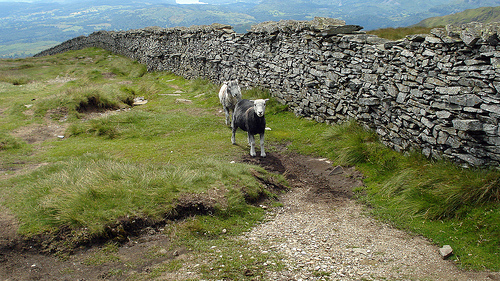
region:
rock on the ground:
[435, 239, 457, 262]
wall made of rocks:
[446, 46, 498, 151]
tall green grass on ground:
[435, 173, 499, 208]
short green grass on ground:
[435, 226, 457, 241]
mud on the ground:
[308, 166, 340, 192]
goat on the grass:
[231, 97, 278, 158]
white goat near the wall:
[211, 78, 242, 109]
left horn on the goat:
[264, 95, 272, 106]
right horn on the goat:
[249, 97, 256, 104]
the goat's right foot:
[243, 131, 258, 156]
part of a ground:
[281, 218, 326, 255]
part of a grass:
[203, 185, 224, 212]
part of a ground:
[327, 237, 352, 272]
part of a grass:
[194, 181, 222, 218]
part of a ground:
[303, 233, 324, 259]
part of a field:
[171, 155, 209, 205]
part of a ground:
[319, 205, 342, 255]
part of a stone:
[436, 236, 448, 267]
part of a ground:
[302, 246, 317, 269]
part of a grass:
[158, 163, 206, 222]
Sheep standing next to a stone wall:
[66, 14, 422, 251]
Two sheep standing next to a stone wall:
[199, 19, 322, 162]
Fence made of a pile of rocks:
[311, 8, 488, 193]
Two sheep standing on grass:
[171, 70, 292, 173]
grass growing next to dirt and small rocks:
[320, 152, 402, 257]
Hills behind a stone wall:
[48, 1, 343, 49]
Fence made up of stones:
[105, 20, 200, 91]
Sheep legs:
[207, 130, 273, 160]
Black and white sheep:
[225, 98, 278, 158]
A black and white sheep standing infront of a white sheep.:
[196, 73, 289, 170]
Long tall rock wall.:
[87, 27, 494, 141]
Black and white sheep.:
[230, 97, 271, 157]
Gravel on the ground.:
[260, 202, 422, 279]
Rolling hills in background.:
[5, 0, 440, 30]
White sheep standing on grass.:
[217, 78, 241, 123]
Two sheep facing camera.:
[216, 79, 268, 161]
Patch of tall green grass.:
[17, 148, 217, 223]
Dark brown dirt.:
[5, 220, 177, 277]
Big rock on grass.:
[437, 237, 452, 262]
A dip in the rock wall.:
[222, 17, 259, 45]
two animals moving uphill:
[13, 7, 480, 272]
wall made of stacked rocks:
[325, 20, 485, 150]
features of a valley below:
[5, 0, 102, 47]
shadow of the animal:
[242, 150, 287, 175]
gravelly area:
[266, 200, 371, 276]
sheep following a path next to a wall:
[195, 65, 330, 160]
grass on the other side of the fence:
[365, 25, 430, 40]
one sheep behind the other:
[200, 70, 300, 166]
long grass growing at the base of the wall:
[325, 112, 470, 177]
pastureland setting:
[20, 7, 481, 263]